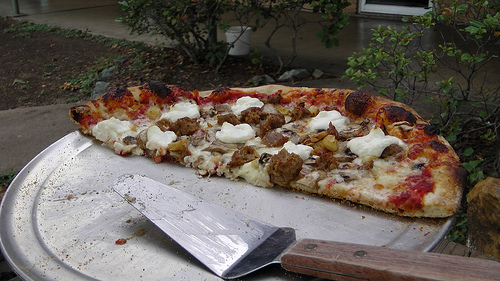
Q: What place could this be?
A: It is a sidewalk.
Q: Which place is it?
A: It is a sidewalk.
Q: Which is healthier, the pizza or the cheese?
A: The cheese is healthier than the pizza.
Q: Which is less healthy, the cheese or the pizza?
A: The pizza is less healthy than the cheese.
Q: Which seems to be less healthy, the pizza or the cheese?
A: The pizza is less healthy than the cheese.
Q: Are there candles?
A: No, there are no candles.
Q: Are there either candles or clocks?
A: No, there are no candles or clocks.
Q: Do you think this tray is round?
A: Yes, the tray is round.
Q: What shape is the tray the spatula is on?
A: The tray is round.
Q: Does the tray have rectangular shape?
A: No, the tray is round.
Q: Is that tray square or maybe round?
A: The tray is round.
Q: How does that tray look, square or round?
A: The tray is round.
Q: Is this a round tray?
A: Yes, this is a round tray.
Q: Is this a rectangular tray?
A: No, this is a round tray.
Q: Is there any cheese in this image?
A: Yes, there is cheese.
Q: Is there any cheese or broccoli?
A: Yes, there is cheese.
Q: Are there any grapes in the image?
A: No, there are no grapes.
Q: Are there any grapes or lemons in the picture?
A: No, there are no grapes or lemons.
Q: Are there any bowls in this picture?
A: No, there are no bowls.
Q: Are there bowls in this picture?
A: No, there are no bowls.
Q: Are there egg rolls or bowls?
A: No, there are no bowls or egg rolls.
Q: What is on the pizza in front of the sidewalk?
A: The sausage is on the pizza.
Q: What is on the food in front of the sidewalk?
A: The sausage is on the pizza.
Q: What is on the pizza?
A: The sausage is on the pizza.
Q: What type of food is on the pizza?
A: The food is a sausage.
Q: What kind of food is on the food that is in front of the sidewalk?
A: The food is a sausage.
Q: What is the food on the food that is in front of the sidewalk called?
A: The food is a sausage.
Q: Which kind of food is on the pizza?
A: The food is a sausage.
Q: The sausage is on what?
A: The sausage is on the pizza.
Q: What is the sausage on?
A: The sausage is on the pizza.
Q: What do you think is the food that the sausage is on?
A: The food is a pizza.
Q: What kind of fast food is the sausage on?
A: The sausage is on the pizza.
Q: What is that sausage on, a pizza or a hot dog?
A: The sausage is on a pizza.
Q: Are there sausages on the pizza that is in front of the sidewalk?
A: Yes, there is a sausage on the pizza.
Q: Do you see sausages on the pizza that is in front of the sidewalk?
A: Yes, there is a sausage on the pizza.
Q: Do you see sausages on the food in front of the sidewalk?
A: Yes, there is a sausage on the pizza.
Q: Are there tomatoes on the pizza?
A: No, there is a sausage on the pizza.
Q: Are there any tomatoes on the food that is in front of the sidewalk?
A: No, there is a sausage on the pizza.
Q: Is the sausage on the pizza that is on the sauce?
A: Yes, the sausage is on the pizza.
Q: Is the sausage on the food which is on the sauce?
A: Yes, the sausage is on the pizza.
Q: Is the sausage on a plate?
A: No, the sausage is on the pizza.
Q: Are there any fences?
A: No, there are no fences.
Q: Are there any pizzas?
A: Yes, there is a pizza.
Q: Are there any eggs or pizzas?
A: Yes, there is a pizza.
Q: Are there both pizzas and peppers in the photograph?
A: No, there is a pizza but no peppers.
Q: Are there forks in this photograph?
A: No, there are no forks.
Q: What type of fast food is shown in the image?
A: The fast food is a pizza.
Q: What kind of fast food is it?
A: The food is a pizza.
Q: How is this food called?
A: This is a pizza.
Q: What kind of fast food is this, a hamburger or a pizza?
A: This is a pizza.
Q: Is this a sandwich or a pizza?
A: This is a pizza.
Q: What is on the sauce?
A: The pizza is on the sauce.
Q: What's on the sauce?
A: The pizza is on the sauce.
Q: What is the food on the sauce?
A: The food is a pizza.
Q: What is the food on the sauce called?
A: The food is a pizza.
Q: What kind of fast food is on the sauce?
A: The food is a pizza.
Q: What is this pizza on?
A: The pizza is on the sauce.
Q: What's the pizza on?
A: The pizza is on the sauce.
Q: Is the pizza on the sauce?
A: Yes, the pizza is on the sauce.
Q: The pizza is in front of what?
A: The pizza is in front of the sidewalk.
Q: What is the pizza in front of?
A: The pizza is in front of the sidewalk.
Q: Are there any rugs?
A: No, there are no rugs.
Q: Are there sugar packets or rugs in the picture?
A: No, there are no rugs or sugar packets.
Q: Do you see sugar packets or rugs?
A: No, there are no rugs or sugar packets.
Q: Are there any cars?
A: No, there are no cars.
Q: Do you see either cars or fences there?
A: No, there are no cars or fences.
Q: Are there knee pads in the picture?
A: No, there are no knee pads.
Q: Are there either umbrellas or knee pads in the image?
A: No, there are no knee pads or umbrellas.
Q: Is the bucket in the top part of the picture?
A: Yes, the bucket is in the top of the image.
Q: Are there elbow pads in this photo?
A: No, there are no elbow pads.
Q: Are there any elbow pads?
A: No, there are no elbow pads.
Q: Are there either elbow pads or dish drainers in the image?
A: No, there are no elbow pads or dish drainers.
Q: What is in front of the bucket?
A: The shrub is in front of the bucket.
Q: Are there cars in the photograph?
A: No, there are no cars.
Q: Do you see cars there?
A: No, there are no cars.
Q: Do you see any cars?
A: No, there are no cars.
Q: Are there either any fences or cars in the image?
A: No, there are no cars or fences.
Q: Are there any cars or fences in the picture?
A: No, there are no cars or fences.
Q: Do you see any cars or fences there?
A: No, there are no cars or fences.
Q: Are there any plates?
A: No, there are no plates.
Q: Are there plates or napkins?
A: No, there are no plates or napkins.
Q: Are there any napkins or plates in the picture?
A: No, there are no plates or napkins.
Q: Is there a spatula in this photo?
A: Yes, there is a spatula.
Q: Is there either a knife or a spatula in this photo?
A: Yes, there is a spatula.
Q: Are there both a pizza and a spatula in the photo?
A: Yes, there are both a spatula and a pizza.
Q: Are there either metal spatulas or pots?
A: Yes, there is a metal spatula.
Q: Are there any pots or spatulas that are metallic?
A: Yes, the spatula is metallic.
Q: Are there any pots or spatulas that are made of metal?
A: Yes, the spatula is made of metal.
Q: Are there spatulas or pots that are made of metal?
A: Yes, the spatula is made of metal.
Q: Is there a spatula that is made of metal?
A: Yes, there is a spatula that is made of metal.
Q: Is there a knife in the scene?
A: No, there are no knives.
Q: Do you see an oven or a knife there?
A: No, there are no knives or ovens.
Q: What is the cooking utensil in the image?
A: The cooking utensil is a spatula.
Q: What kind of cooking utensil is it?
A: The cooking utensil is a spatula.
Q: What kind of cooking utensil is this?
A: That is a spatula.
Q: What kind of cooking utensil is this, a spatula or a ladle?
A: That is a spatula.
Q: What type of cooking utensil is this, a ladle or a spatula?
A: That is a spatula.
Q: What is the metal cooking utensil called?
A: The cooking utensil is a spatula.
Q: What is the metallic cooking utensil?
A: The cooking utensil is a spatula.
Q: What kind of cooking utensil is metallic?
A: The cooking utensil is a spatula.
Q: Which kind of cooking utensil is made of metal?
A: The cooking utensil is a spatula.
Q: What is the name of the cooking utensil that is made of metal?
A: The cooking utensil is a spatula.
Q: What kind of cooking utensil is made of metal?
A: The cooking utensil is a spatula.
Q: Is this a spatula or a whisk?
A: This is a spatula.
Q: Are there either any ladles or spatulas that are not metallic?
A: No, there is a spatula but it is metallic.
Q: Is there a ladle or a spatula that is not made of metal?
A: No, there is a spatula but it is made of metal.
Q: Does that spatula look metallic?
A: Yes, the spatula is metallic.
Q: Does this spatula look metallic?
A: Yes, the spatula is metallic.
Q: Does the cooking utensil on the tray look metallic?
A: Yes, the spatula is metallic.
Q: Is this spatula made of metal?
A: Yes, the spatula is made of metal.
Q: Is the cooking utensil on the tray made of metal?
A: Yes, the spatula is made of metal.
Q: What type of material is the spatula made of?
A: The spatula is made of metal.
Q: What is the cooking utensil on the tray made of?
A: The spatula is made of metal.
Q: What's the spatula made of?
A: The spatula is made of metal.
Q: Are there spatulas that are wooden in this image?
A: No, there is a spatula but it is metallic.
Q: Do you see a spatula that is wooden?
A: No, there is a spatula but it is metallic.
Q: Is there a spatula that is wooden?
A: No, there is a spatula but it is metallic.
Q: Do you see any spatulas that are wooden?
A: No, there is a spatula but it is metallic.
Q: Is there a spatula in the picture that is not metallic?
A: No, there is a spatula but it is metallic.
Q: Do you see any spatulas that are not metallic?
A: No, there is a spatula but it is metallic.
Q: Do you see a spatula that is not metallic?
A: No, there is a spatula but it is metallic.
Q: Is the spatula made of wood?
A: No, the spatula is made of metal.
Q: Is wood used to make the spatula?
A: No, the spatula is made of metal.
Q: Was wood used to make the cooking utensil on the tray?
A: No, the spatula is made of metal.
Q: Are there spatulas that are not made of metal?
A: No, there is a spatula but it is made of metal.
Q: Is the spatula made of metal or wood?
A: The spatula is made of metal.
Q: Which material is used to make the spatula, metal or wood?
A: The spatula is made of metal.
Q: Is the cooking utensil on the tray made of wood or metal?
A: The spatula is made of metal.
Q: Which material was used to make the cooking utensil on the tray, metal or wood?
A: The spatula is made of metal.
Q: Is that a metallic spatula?
A: Yes, that is a metallic spatula.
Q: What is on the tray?
A: The spatula is on the tray.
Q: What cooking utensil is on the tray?
A: The cooking utensil is a spatula.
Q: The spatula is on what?
A: The spatula is on the tray.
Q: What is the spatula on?
A: The spatula is on the tray.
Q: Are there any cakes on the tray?
A: No, there is a spatula on the tray.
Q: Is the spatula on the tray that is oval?
A: Yes, the spatula is on the tray.